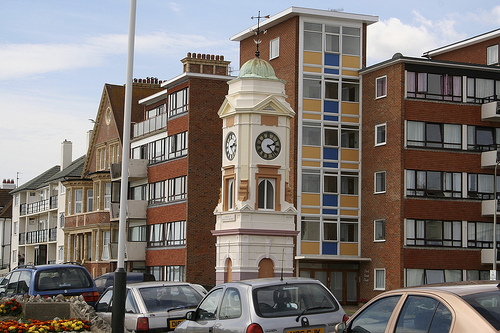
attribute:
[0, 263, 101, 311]
van — parked, blue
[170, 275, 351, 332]
car — silver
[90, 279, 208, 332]
car — hatchback, silver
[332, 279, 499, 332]
car — beige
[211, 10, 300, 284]
tower — stone, tall, white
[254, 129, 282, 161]
clock — black, white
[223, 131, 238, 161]
clock — black, white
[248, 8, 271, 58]
vane — weather, metal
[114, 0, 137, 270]
pole — white, tall, metal, thin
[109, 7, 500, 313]
building — tall, brick, multilevel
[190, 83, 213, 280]
bricks — red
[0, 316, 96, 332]
flowers — yellow, orange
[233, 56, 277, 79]
top — rounded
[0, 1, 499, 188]
sky — cloudy, blue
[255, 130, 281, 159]
clockface — large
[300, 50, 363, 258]
facade — blue, orange, yellow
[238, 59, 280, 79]
dome — green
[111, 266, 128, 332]
base — green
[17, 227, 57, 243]
fence — black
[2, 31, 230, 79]
cloud — white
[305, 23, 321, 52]
curtain — white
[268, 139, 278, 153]
hands — black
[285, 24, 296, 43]
brick — red